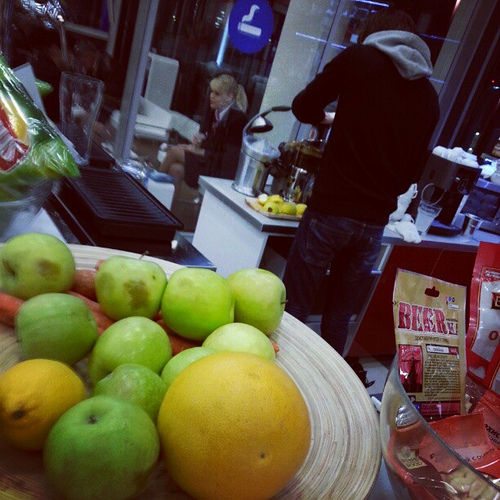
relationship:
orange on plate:
[157, 350, 312, 496] [4, 242, 380, 497]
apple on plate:
[42, 395, 161, 497] [4, 242, 380, 497]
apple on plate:
[96, 364, 168, 422] [4, 242, 380, 497]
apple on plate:
[90, 315, 171, 377] [4, 242, 380, 497]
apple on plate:
[162, 267, 234, 342] [4, 242, 380, 497]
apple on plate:
[95, 255, 167, 321] [4, 242, 380, 497]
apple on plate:
[14, 291, 98, 363] [4, 242, 380, 497]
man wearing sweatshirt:
[281, 4, 442, 356] [290, 29, 441, 227]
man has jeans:
[281, 4, 442, 356] [282, 206, 387, 359]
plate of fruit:
[278, 321, 396, 494] [108, 257, 283, 429]